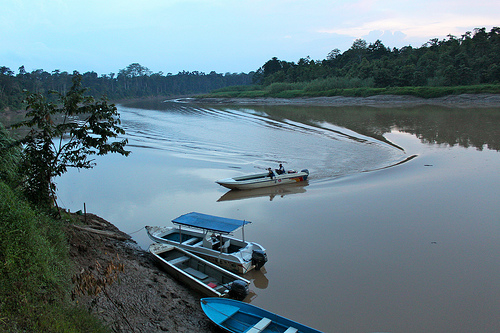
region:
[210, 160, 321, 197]
the boat on the water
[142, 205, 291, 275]
the boat on the water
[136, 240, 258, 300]
the boat on the water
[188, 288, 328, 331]
the boat on the water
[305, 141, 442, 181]
the wake of the boat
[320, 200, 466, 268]
the water is calm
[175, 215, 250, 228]
the canopy over the boat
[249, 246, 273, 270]
the motor on the boat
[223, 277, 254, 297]
the motor on the boat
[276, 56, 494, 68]
the trees with green leaves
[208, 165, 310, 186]
The white boat in the middle of the water.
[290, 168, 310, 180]
The design on the white boat.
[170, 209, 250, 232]
The blue canopy on the boat.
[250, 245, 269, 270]
The engine of the boat with the blue canopy.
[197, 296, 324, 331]
The blue boat on the shoreline.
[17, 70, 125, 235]
The tree on the left.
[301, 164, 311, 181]
The engine on the back of the white boat in the water.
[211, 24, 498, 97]
The trees on the right.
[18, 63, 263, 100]
The trees in the distance.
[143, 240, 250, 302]
The boat on the left of the boat with a canopy.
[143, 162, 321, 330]
the group of boats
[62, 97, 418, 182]
the ripple in the water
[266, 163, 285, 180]
the boat on the water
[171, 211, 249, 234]
the roof on the boat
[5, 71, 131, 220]
the tree near the water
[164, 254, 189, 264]
the seat on the boat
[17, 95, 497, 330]
the body of water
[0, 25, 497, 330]
the trees along the water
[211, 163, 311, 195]
long white boat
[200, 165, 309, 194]
boat in the water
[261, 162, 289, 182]
two people sitting in a boat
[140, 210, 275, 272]
boat with blue cover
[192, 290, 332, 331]
blue rowboat on the shore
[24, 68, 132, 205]
tree with green leaves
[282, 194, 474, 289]
calm murky brown water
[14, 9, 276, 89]
clear blue cloudless sky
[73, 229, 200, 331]
brown mud by the water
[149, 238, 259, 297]
small white rowboat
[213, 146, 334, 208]
The boat is in the water.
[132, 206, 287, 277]
The is in the water.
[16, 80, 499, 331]
The water is calm.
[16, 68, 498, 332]
The water is peaceful.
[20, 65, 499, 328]
The water is tranquil.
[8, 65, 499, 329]
The water is serene.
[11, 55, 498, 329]
The water is even-tempered.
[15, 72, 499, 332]
The water is mellow.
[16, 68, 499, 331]
The water is sudued.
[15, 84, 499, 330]
The water is placid.